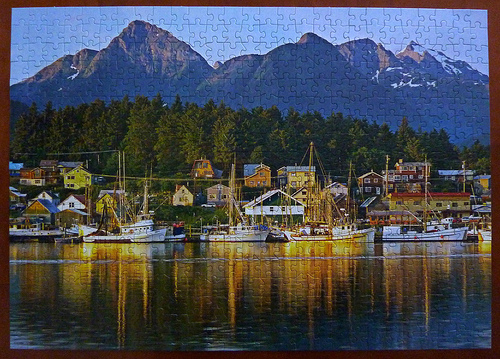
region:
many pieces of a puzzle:
[11, 13, 491, 344]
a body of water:
[13, 243, 479, 349]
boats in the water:
[15, 215, 483, 250]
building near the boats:
[256, 190, 312, 219]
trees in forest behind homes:
[11, 93, 493, 160]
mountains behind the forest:
[18, 22, 485, 125]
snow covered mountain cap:
[410, 42, 470, 79]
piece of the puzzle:
[416, 21, 443, 44]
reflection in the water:
[66, 238, 484, 285]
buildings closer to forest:
[242, 160, 318, 188]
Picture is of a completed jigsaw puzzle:
[9, 7, 492, 352]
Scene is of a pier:
[8, 149, 495, 242]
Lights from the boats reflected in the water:
[10, 238, 495, 313]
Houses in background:
[18, 158, 493, 198]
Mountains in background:
[13, 16, 498, 116]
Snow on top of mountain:
[369, 39, 472, 91]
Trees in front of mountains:
[7, 98, 490, 178]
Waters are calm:
[8, 237, 492, 348]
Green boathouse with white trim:
[243, 191, 307, 233]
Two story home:
[242, 160, 274, 192]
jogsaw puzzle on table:
[13, 5, 496, 350]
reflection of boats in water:
[124, 240, 444, 357]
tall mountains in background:
[82, 13, 484, 121]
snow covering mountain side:
[412, 45, 447, 82]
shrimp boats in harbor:
[79, 200, 487, 252]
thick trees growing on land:
[56, 85, 386, 164]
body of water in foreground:
[46, 240, 447, 347]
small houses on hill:
[183, 159, 331, 198]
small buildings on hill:
[27, 164, 121, 200]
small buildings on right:
[367, 136, 492, 211]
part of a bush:
[289, 84, 306, 119]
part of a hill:
[247, 82, 263, 134]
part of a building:
[276, 193, 298, 243]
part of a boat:
[303, 223, 308, 230]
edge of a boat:
[293, 209, 303, 229]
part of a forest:
[282, 116, 292, 133]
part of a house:
[411, 178, 418, 196]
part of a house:
[262, 195, 270, 207]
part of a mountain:
[300, 65, 317, 87]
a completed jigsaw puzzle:
[4, 2, 496, 354]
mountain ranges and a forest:
[12, 12, 494, 138]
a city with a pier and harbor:
[2, 141, 483, 262]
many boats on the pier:
[0, 139, 488, 251]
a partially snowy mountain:
[375, 39, 486, 98]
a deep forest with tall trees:
[12, 87, 496, 209]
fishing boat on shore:
[75, 174, 195, 249]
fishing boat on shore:
[365, 171, 478, 246]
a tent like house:
[236, 186, 308, 222]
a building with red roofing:
[378, 182, 475, 216]